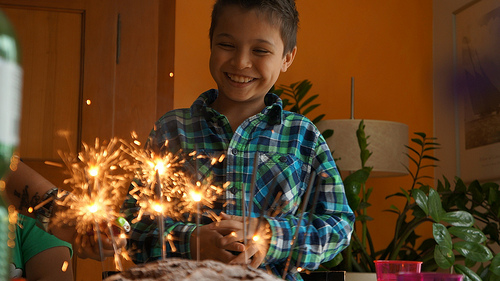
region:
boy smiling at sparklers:
[117, 2, 357, 279]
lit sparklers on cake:
[53, 132, 223, 277]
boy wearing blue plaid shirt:
[121, 2, 357, 270]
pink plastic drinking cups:
[373, 256, 463, 278]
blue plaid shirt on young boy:
[116, 87, 355, 271]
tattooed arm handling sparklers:
[4, 154, 127, 260]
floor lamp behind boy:
[316, 74, 409, 257]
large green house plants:
[351, 122, 498, 279]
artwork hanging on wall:
[429, 3, 499, 198]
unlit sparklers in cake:
[239, 148, 325, 278]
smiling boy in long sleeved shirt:
[132, 5, 354, 262]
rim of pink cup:
[370, 248, 424, 277]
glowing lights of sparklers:
[58, 141, 228, 241]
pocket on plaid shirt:
[240, 149, 310, 216]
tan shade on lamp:
[315, 114, 418, 176]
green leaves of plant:
[418, 199, 469, 253]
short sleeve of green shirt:
[17, 231, 73, 276]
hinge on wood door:
[105, 13, 132, 73]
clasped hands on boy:
[196, 214, 270, 273]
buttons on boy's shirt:
[219, 141, 250, 203]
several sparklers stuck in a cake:
[42, 129, 269, 276]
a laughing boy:
[118, 2, 368, 279]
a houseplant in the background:
[269, 121, 499, 279]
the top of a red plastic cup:
[370, 255, 429, 279]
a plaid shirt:
[111, 90, 363, 280]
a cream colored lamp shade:
[307, 95, 413, 188]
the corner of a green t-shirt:
[1, 202, 79, 264]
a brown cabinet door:
[10, 3, 140, 276]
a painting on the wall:
[420, 2, 499, 240]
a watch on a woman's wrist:
[30, 166, 74, 251]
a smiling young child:
[146, 1, 354, 274]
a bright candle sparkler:
[179, 179, 213, 264]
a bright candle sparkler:
[137, 195, 177, 261]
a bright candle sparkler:
[139, 149, 175, 197]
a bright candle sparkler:
[62, 189, 121, 274]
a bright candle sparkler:
[62, 139, 117, 193]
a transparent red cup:
[370, 257, 422, 279]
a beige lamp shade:
[315, 118, 408, 175]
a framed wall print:
[430, 0, 499, 196]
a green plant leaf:
[431, 222, 454, 253]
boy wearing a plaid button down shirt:
[138, 0, 353, 267]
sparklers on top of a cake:
[79, 131, 247, 271]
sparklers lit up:
[66, 128, 243, 274]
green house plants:
[333, 137, 489, 261]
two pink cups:
[373, 243, 465, 278]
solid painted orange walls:
[367, 18, 413, 109]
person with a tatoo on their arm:
[12, 166, 53, 232]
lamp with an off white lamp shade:
[321, 96, 408, 261]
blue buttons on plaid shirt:
[224, 141, 249, 208]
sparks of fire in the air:
[66, 68, 181, 120]